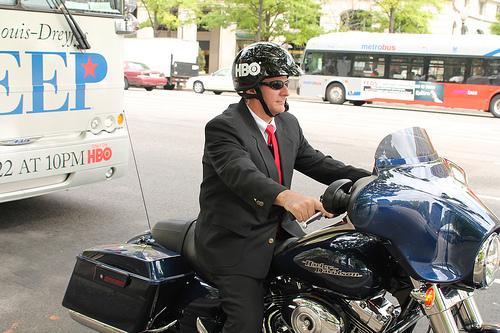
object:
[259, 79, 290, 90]
sunglasses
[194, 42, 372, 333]
man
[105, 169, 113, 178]
light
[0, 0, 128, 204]
bus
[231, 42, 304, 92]
helmet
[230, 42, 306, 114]
head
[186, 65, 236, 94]
white car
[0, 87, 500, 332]
street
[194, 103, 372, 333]
suit